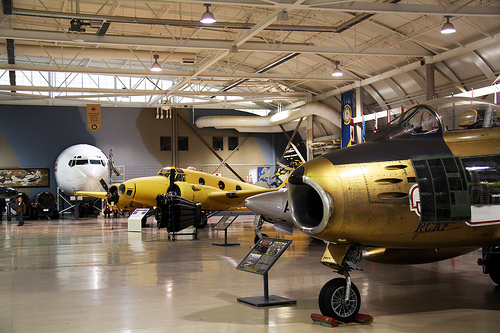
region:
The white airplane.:
[37, 140, 121, 210]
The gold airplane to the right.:
[227, 101, 488, 293]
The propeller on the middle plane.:
[94, 179, 124, 208]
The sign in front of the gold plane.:
[225, 232, 292, 318]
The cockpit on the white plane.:
[67, 150, 112, 169]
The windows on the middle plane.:
[177, 164, 251, 197]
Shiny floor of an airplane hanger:
[57, 254, 175, 321]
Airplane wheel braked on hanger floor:
[311, 271, 380, 330]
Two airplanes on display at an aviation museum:
[52, 142, 249, 243]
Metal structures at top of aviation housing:
[31, 55, 148, 104]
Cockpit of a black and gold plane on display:
[298, 107, 495, 226]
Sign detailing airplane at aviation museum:
[233, 235, 301, 312]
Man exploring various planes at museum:
[13, 196, 28, 224]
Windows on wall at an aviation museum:
[153, 128, 252, 159]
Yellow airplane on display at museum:
[98, 163, 240, 214]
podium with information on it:
[235, 236, 297, 308]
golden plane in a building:
[287, 98, 498, 320]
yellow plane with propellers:
[73, 163, 290, 211]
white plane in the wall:
[54, 141, 111, 198]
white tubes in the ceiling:
[194, 99, 346, 134]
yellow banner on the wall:
[85, 102, 103, 134]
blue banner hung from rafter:
[339, 91, 355, 149]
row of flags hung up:
[347, 104, 410, 144]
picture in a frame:
[1, 166, 51, 188]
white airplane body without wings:
[52, 141, 116, 198]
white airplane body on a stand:
[50, 140, 120, 220]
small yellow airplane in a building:
[73, 160, 290, 224]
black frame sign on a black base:
[234, 231, 296, 308]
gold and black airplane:
[282, 92, 498, 322]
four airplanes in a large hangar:
[0, 0, 497, 330]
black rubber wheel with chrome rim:
[317, 275, 362, 320]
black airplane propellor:
[95, 176, 122, 215]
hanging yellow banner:
[82, 102, 104, 132]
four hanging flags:
[343, 102, 390, 144]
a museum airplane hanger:
[3, 5, 488, 320]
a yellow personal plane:
[61, 120, 278, 242]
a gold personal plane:
[237, 57, 494, 322]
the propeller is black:
[82, 170, 137, 212]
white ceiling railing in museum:
[15, 7, 481, 142]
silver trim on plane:
[231, 165, 341, 242]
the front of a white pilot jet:
[50, 138, 118, 219]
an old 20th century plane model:
[239, 88, 499, 328]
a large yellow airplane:
[67, 163, 271, 245]